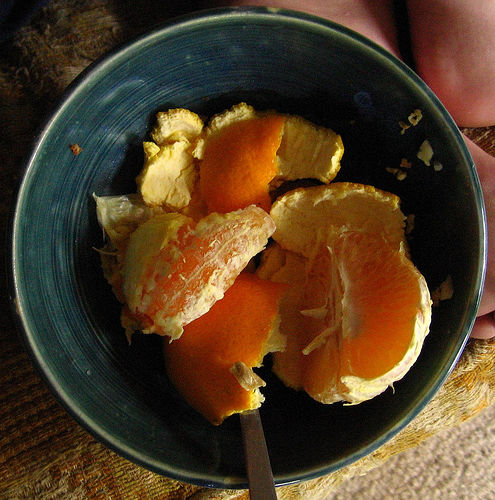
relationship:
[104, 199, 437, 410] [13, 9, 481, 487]
orange in a bowl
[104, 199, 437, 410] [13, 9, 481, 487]
orange on sides of bowl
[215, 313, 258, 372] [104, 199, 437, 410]
peel on orange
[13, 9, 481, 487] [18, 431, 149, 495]
bowl on counter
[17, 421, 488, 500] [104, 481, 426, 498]
carpet on ground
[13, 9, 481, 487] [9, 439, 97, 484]
bowl on mat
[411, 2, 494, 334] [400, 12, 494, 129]
person seen feet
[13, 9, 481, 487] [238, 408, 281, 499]
bowl has utensil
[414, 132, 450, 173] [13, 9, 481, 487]
chip in bowl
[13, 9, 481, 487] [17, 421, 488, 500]
bowl on top a couch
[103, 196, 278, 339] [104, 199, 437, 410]
meat of orange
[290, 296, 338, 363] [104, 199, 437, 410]
seed of orange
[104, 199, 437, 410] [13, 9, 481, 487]
orange in bowl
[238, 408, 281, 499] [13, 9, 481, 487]
spoon in bowl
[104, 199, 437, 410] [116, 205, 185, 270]
oranges have white skin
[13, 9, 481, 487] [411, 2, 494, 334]
bowl next to feet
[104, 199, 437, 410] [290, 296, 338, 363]
orange has seeds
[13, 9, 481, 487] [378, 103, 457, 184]
bowl has spots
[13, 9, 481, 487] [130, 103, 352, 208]
bowl has peels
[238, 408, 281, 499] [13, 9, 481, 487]
utensil leaning on bowl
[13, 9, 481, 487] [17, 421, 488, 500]
bowl on top of fabric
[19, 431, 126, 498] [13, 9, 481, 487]
stripes around bowl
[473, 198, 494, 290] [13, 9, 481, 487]
light shining on bowl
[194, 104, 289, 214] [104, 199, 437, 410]
peel of orange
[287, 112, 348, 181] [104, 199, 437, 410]
peal of orange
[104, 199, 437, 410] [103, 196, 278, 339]
orange in a segment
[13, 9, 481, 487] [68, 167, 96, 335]
bowl has lines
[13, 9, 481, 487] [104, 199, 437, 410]
bowl with orange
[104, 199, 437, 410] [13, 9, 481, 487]
oranges in a bowl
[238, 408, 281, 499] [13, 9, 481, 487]
spoon in bow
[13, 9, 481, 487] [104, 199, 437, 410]
bowl has fruit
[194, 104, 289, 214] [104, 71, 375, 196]
peel on side